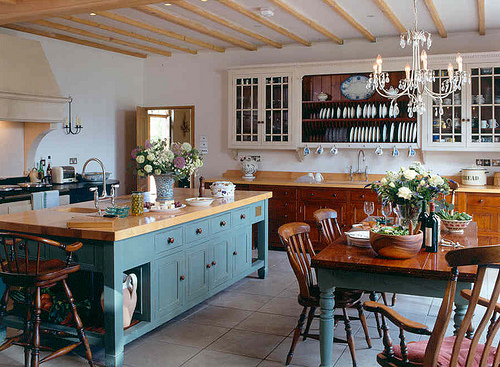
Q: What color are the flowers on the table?
A: Yellow.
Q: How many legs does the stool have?
A: Four.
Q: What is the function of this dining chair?
A: Sitting.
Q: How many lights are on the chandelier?
A: Six.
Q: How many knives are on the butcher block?
A: One.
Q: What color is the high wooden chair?
A: Dark Brown.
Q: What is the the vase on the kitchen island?
A: Flowers.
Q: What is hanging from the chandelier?
A: Fake crystals.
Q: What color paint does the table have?
A: Blue.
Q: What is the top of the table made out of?
A: Wood.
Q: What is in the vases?
A: Flowers.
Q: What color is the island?
A: Blue.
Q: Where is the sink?
A: On the island.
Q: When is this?
A: Day time.